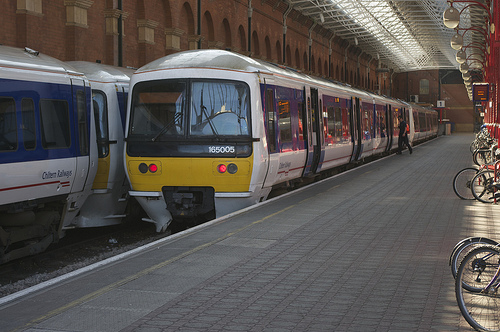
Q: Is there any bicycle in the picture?
A: Yes, there are bicycles.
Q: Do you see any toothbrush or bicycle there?
A: Yes, there are bicycles.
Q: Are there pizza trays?
A: No, there are no pizza trays.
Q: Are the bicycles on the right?
A: Yes, the bicycles are on the right of the image.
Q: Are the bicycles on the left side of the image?
A: No, the bicycles are on the right of the image.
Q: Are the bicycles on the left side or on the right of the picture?
A: The bicycles are on the right of the image.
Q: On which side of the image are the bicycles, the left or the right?
A: The bicycles are on the right of the image.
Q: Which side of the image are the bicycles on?
A: The bicycles are on the right of the image.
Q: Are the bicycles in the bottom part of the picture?
A: Yes, the bicycles are in the bottom of the image.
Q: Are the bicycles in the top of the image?
A: No, the bicycles are in the bottom of the image.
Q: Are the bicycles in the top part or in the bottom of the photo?
A: The bicycles are in the bottom of the image.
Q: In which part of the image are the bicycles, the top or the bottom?
A: The bicycles are in the bottom of the image.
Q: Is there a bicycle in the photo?
A: Yes, there is a bicycle.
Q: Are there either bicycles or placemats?
A: Yes, there is a bicycle.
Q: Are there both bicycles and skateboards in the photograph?
A: No, there is a bicycle but no skateboards.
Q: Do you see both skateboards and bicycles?
A: No, there is a bicycle but no skateboards.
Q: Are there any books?
A: No, there are no books.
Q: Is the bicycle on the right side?
A: Yes, the bicycle is on the right of the image.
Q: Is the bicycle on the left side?
A: No, the bicycle is on the right of the image.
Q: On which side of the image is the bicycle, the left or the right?
A: The bicycle is on the right of the image.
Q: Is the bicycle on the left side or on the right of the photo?
A: The bicycle is on the right of the image.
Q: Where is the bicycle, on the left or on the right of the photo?
A: The bicycle is on the right of the image.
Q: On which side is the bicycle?
A: The bicycle is on the right of the image.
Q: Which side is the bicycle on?
A: The bicycle is on the right of the image.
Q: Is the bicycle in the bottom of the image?
A: Yes, the bicycle is in the bottom of the image.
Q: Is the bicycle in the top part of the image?
A: No, the bicycle is in the bottom of the image.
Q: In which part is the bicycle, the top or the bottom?
A: The bicycle is in the bottom of the image.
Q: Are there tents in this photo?
A: No, there are no tents.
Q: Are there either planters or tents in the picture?
A: No, there are no tents or planters.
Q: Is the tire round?
A: Yes, the tire is round.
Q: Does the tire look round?
A: Yes, the tire is round.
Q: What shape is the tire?
A: The tire is round.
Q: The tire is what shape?
A: The tire is round.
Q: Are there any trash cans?
A: No, there are no trash cans.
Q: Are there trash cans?
A: No, there are no trash cans.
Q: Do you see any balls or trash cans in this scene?
A: No, there are no trash cans or balls.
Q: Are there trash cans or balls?
A: No, there are no trash cans or balls.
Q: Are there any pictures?
A: No, there are no pictures.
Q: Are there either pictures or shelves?
A: No, there are no pictures or shelves.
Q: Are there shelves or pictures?
A: No, there are no pictures or shelves.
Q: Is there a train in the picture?
A: Yes, there is a train.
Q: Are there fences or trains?
A: Yes, there is a train.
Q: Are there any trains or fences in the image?
A: Yes, there is a train.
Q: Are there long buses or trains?
A: Yes, there is a long train.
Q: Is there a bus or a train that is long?
A: Yes, the train is long.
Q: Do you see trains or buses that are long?
A: Yes, the train is long.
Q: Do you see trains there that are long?
A: Yes, there is a long train.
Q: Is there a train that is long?
A: Yes, there is a train that is long.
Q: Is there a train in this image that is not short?
A: Yes, there is a long train.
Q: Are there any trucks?
A: No, there are no trucks.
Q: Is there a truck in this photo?
A: No, there are no trucks.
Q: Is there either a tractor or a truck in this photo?
A: No, there are no trucks or tractors.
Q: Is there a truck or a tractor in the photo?
A: No, there are no trucks or tractors.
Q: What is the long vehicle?
A: The vehicle is a train.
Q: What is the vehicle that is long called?
A: The vehicle is a train.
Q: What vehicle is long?
A: The vehicle is a train.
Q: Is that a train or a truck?
A: That is a train.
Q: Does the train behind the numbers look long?
A: Yes, the train is long.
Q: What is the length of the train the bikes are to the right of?
A: The train is long.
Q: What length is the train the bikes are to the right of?
A: The train is long.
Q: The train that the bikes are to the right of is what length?
A: The train is long.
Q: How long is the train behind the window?
A: The train is long.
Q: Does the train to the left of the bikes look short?
A: No, the train is long.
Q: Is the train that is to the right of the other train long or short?
A: The train is long.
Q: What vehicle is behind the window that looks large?
A: The vehicle is a train.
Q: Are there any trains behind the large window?
A: Yes, there is a train behind the window.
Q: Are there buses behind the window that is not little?
A: No, there is a train behind the window.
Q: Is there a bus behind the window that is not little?
A: No, there is a train behind the window.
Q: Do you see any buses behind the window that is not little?
A: No, there is a train behind the window.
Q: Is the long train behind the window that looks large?
A: Yes, the train is behind the window.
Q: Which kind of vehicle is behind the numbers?
A: The vehicle is a train.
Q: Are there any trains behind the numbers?
A: Yes, there is a train behind the numbers.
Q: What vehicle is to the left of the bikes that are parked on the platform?
A: The vehicle is a train.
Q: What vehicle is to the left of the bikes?
A: The vehicle is a train.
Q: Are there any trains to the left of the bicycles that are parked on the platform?
A: Yes, there is a train to the left of the bicycles.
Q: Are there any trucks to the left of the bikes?
A: No, there is a train to the left of the bikes.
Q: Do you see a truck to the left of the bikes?
A: No, there is a train to the left of the bikes.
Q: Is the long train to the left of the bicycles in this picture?
A: Yes, the train is to the left of the bicycles.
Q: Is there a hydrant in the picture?
A: No, there are no fire hydrants.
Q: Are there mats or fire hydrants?
A: No, there are no fire hydrants or mats.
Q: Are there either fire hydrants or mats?
A: No, there are no fire hydrants or mats.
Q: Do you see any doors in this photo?
A: Yes, there is a door.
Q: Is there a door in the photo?
A: Yes, there is a door.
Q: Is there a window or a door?
A: Yes, there is a door.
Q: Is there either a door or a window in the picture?
A: Yes, there is a door.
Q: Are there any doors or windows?
A: Yes, there is a door.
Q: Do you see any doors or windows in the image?
A: Yes, there is a door.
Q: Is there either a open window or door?
A: Yes, there is an open door.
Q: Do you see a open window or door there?
A: Yes, there is an open door.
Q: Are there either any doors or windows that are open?
A: Yes, the door is open.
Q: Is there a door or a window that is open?
A: Yes, the door is open.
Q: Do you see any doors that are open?
A: Yes, there is an open door.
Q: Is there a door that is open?
A: Yes, there is a door that is open.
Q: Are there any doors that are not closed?
A: Yes, there is a open door.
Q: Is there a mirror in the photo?
A: No, there are no mirrors.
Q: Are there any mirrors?
A: No, there are no mirrors.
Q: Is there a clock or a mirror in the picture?
A: No, there are no mirrors or clocks.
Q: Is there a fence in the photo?
A: No, there are no fences.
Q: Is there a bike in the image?
A: Yes, there are bikes.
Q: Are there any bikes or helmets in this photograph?
A: Yes, there are bikes.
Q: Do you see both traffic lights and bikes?
A: No, there are bikes but no traffic lights.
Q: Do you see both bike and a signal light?
A: No, there are bikes but no traffic lights.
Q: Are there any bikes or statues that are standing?
A: Yes, the bikes are standing.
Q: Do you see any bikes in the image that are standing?
A: Yes, there are bikes that are standing.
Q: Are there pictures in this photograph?
A: No, there are no pictures.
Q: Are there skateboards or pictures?
A: No, there are no pictures or skateboards.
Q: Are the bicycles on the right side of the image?
A: Yes, the bicycles are on the right of the image.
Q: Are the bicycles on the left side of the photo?
A: No, the bicycles are on the right of the image.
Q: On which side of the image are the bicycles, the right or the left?
A: The bicycles are on the right of the image.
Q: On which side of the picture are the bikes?
A: The bikes are on the right of the image.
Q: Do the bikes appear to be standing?
A: Yes, the bikes are standing.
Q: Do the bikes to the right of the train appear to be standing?
A: Yes, the bicycles are standing.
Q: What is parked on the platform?
A: The bicycles are parked on the platform.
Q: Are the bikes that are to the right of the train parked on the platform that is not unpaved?
A: Yes, the bikes are parked on the platform.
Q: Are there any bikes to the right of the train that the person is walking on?
A: Yes, there are bikes to the right of the train.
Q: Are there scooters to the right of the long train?
A: No, there are bikes to the right of the train.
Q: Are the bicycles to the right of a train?
A: Yes, the bicycles are to the right of a train.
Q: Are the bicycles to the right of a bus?
A: No, the bicycles are to the right of a train.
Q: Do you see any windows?
A: Yes, there is a window.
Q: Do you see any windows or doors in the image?
A: Yes, there is a window.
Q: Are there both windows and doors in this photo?
A: Yes, there are both a window and a door.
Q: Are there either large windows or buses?
A: Yes, there is a large window.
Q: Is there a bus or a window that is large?
A: Yes, the window is large.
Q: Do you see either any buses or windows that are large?
A: Yes, the window is large.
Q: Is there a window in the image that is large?
A: Yes, there is a large window.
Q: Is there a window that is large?
A: Yes, there is a window that is large.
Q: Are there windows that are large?
A: Yes, there is a window that is large.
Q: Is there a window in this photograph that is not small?
A: Yes, there is a large window.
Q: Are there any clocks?
A: No, there are no clocks.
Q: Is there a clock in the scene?
A: No, there are no clocks.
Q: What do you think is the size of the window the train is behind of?
A: The window is large.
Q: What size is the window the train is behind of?
A: The window is large.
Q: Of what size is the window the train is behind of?
A: The window is large.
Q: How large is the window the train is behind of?
A: The window is large.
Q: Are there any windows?
A: Yes, there is a window.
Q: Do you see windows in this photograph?
A: Yes, there is a window.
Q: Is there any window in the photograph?
A: Yes, there is a window.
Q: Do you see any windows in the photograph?
A: Yes, there is a window.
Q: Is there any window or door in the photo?
A: Yes, there is a window.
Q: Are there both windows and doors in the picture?
A: Yes, there are both a window and a door.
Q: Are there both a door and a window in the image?
A: Yes, there are both a window and a door.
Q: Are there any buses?
A: No, there are no buses.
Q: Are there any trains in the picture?
A: Yes, there is a train.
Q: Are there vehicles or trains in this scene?
A: Yes, there is a train.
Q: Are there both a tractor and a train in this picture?
A: No, there is a train but no tractors.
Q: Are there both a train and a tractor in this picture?
A: No, there is a train but no tractors.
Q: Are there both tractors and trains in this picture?
A: No, there is a train but no tractors.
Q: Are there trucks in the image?
A: No, there are no trucks.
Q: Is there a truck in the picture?
A: No, there are no trucks.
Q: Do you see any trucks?
A: No, there are no trucks.